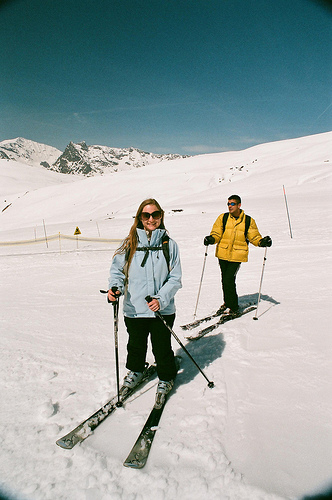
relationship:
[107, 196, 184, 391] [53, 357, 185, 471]
person on skis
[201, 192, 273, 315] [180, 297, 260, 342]
person on skis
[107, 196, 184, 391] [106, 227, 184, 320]
person wearing jacket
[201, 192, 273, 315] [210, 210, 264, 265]
person wearing jacket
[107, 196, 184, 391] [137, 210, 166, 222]
person wearing sunglasses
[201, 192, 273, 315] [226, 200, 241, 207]
person wearing sunglasses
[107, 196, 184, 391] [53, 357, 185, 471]
person wearing skis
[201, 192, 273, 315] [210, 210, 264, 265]
person with jacket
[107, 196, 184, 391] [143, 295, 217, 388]
person holding ski pole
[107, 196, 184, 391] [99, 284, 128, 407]
person holding ski pole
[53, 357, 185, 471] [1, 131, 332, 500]
skis are in snow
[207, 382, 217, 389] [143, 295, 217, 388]
tip of ski pole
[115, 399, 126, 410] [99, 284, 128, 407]
tip of ski pole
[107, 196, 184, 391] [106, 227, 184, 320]
person in jacket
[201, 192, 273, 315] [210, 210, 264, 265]
person in jacket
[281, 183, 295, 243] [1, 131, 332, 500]
pole in snow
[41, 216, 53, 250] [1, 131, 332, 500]
pole in snow